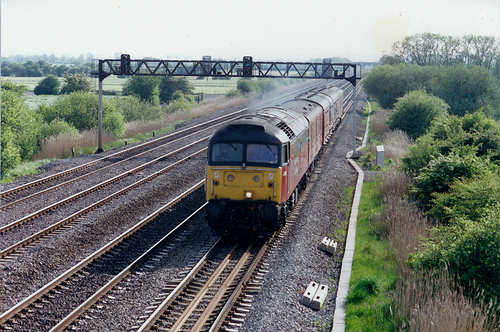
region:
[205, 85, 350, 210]
the train is black and red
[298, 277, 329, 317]
stones are on the side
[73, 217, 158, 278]
gravel is between the tracks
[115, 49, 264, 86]
traffic light is above the train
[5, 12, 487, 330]
the photo was taken during the day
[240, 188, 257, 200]
the train light is on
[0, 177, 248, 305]
four sets of train trucks are on the rainroad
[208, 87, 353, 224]
the train is a cargo train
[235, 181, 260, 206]
this is the head lump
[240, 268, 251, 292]
this is a metal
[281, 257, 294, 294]
these are small rocks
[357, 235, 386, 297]
this is a grass area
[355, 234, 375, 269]
the grass is green in color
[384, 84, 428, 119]
this is a tree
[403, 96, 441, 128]
the leaves are green in color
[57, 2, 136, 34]
this is the sky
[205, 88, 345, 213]
yellow and red train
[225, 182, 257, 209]
white light on train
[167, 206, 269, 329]
train on brown track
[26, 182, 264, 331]
grey gravel in tracks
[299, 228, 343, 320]
wooden ties near tracks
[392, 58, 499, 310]
green trees next to tracks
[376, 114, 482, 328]
brown and reedy plants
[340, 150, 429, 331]
green grass near tracks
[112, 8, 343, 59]
grey and cloudy sky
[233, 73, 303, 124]
steam rising from train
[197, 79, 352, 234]
this is a train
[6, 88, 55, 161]
this is a shrub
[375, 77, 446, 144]
this is a shrub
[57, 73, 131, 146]
this is a shrub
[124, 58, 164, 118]
this is a shrub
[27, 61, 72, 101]
this is a shrub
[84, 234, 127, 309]
this is a railway line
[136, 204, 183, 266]
this is a railway line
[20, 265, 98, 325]
this is a railway line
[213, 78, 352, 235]
red and yellow train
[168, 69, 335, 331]
train on brown track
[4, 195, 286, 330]
grey gravel between tracks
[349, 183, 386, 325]
green grass is thick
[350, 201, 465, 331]
brown reeds near track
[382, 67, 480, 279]
green trees along track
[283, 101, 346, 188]
side of train is red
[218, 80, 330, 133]
top of cars is black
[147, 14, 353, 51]
grey and cloudy sky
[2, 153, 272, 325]
four sets of train tracks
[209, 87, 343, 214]
train is yellow and red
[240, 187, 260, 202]
train has front light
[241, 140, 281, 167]
train has front window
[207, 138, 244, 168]
train has front window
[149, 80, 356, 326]
train is on train track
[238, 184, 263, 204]
train front light is on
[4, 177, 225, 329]
train track is brown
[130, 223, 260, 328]
train track is brown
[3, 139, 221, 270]
train track is brown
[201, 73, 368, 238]
red and yellow train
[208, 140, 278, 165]
black widnshield in front of train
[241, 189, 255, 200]
round bright front light on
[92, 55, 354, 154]
black poles with black traffic lights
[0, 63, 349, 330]
metal rusty train tracks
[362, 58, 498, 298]
a bunch of green bushes in right side